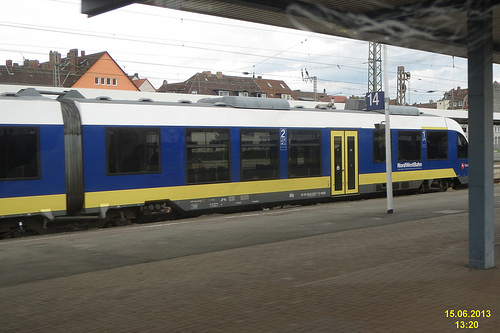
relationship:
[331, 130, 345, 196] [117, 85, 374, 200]
door on train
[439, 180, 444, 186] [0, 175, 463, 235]
part of wheels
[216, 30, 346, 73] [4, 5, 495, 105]
clouds in sky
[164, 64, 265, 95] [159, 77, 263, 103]
roof on house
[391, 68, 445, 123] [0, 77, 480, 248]
tower beyond train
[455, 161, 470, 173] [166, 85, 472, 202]
sticker on train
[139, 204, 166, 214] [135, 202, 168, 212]
part of wheel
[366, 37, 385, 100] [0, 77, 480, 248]
tower behind train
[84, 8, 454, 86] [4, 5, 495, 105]
clouds in sky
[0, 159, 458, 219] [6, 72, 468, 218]
stripe of bus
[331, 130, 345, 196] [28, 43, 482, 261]
door on train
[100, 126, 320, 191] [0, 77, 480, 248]
windows on train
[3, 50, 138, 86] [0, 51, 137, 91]
roof on building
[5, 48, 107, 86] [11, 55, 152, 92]
roof on building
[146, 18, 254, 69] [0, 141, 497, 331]
sky above land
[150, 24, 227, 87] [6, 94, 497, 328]
wires above land